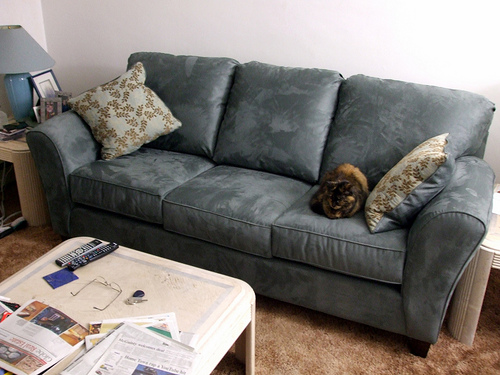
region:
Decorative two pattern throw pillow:
[65, 60, 185, 165]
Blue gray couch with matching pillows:
[23, 51, 498, 264]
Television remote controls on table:
[47, 230, 123, 275]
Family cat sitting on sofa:
[277, 154, 386, 229]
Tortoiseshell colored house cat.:
[307, 159, 370, 223]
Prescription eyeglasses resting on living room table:
[68, 270, 128, 311]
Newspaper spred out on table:
[0, 306, 202, 373]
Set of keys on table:
[121, 285, 152, 310]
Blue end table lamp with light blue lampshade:
[0, 22, 61, 122]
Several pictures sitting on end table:
[28, 69, 75, 128]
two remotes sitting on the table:
[37, 233, 119, 285]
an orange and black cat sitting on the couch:
[285, 147, 392, 236]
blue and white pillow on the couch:
[353, 96, 466, 248]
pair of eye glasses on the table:
[63, 265, 133, 327]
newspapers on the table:
[74, 300, 206, 373]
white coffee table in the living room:
[35, 225, 272, 352]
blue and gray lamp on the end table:
[0, 21, 82, 138]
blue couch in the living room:
[37, 24, 499, 353]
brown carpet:
[276, 322, 357, 354]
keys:
[117, 278, 154, 319]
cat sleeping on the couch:
[280, 147, 377, 249]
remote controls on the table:
[53, 237, 113, 270]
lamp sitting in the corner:
[0, 21, 62, 151]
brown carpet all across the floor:
[6, 220, 482, 373]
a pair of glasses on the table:
[66, 270, 118, 322]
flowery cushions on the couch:
[73, 65, 443, 243]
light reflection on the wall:
[396, 2, 499, 93]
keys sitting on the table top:
[121, 273, 155, 317]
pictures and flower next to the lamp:
[27, 48, 79, 133]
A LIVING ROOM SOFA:
[23, 48, 499, 356]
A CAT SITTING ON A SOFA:
[305, 151, 385, 240]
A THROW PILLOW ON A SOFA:
[63, 55, 187, 168]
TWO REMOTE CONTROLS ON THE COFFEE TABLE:
[51, 229, 123, 277]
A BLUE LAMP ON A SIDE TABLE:
[3, 52, 58, 126]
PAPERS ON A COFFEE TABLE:
[7, 295, 205, 374]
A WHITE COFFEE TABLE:
[28, 243, 275, 373]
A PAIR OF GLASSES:
[61, 267, 133, 318]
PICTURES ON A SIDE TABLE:
[24, 67, 78, 124]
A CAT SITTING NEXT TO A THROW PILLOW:
[301, 110, 477, 241]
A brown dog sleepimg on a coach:
[312, 158, 367, 220]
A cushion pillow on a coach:
[63, 81, 179, 133]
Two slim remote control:
[55, 235, 115, 260]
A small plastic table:
[30, 231, 261, 352]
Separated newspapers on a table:
[76, 310, 181, 370]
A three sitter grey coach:
[20, 71, 485, 303]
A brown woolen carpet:
[280, 320, 455, 370]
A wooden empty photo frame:
[31, 67, 62, 97]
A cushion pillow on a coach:
[382, 158, 453, 234]